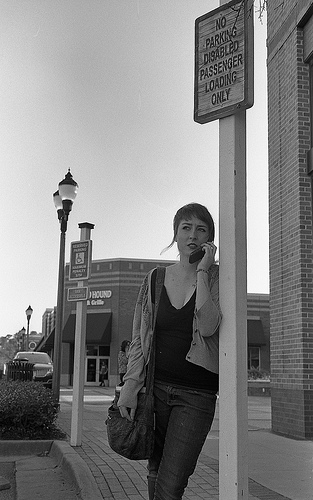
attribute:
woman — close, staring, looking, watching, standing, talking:
[140, 200, 238, 469]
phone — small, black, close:
[187, 243, 222, 273]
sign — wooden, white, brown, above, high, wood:
[181, 14, 260, 122]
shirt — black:
[158, 297, 222, 400]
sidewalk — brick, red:
[55, 431, 147, 496]